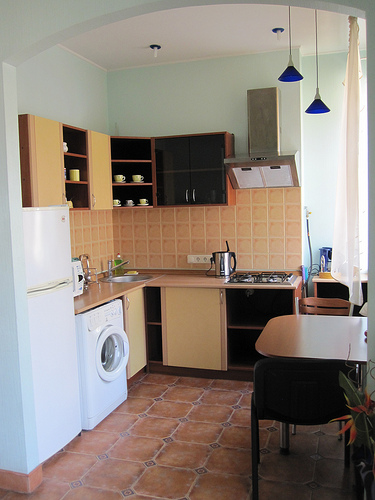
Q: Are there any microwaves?
A: Yes, there is a microwave.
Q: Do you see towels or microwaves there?
A: Yes, there is a microwave.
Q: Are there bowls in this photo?
A: No, there are no bowls.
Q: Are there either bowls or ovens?
A: No, there are no bowls or ovens.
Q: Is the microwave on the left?
A: Yes, the microwave is on the left of the image.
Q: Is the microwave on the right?
A: No, the microwave is on the left of the image.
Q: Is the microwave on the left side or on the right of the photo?
A: The microwave is on the left of the image.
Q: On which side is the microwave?
A: The microwave is on the left of the image.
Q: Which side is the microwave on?
A: The microwave is on the left of the image.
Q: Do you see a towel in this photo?
A: No, there are no towels.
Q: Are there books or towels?
A: No, there are no towels or books.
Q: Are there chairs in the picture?
A: Yes, there is a chair.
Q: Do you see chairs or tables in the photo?
A: Yes, there is a chair.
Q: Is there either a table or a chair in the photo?
A: Yes, there is a chair.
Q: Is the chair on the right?
A: Yes, the chair is on the right of the image.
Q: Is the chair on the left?
A: No, the chair is on the right of the image.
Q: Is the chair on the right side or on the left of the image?
A: The chair is on the right of the image.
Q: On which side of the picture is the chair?
A: The chair is on the right of the image.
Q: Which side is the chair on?
A: The chair is on the right of the image.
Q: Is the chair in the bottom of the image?
A: Yes, the chair is in the bottom of the image.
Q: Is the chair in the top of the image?
A: No, the chair is in the bottom of the image.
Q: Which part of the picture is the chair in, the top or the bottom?
A: The chair is in the bottom of the image.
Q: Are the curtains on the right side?
A: Yes, the curtains are on the right of the image.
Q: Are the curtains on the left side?
A: No, the curtains are on the right of the image.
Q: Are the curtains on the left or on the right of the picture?
A: The curtains are on the right of the image.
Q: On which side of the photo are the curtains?
A: The curtains are on the right of the image.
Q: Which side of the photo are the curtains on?
A: The curtains are on the right of the image.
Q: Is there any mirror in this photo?
A: No, there are no mirrors.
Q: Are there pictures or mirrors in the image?
A: No, there are no mirrors or pictures.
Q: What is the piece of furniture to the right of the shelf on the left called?
A: The piece of furniture is a cupboard.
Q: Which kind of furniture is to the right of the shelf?
A: The piece of furniture is a cupboard.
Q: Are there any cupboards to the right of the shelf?
A: Yes, there is a cupboard to the right of the shelf.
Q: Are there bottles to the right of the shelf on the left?
A: No, there is a cupboard to the right of the shelf.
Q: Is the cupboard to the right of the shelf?
A: Yes, the cupboard is to the right of the shelf.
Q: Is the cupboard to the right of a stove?
A: No, the cupboard is to the right of the shelf.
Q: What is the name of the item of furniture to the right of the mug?
A: The piece of furniture is a cupboard.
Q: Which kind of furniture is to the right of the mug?
A: The piece of furniture is a cupboard.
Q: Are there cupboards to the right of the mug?
A: Yes, there is a cupboard to the right of the mug.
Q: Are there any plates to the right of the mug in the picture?
A: No, there is a cupboard to the right of the mug.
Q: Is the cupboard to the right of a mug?
A: Yes, the cupboard is to the right of a mug.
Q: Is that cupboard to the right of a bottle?
A: No, the cupboard is to the right of a mug.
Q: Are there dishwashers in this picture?
A: Yes, there is a dishwasher.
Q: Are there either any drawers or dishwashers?
A: Yes, there is a dishwasher.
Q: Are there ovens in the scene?
A: No, there are no ovens.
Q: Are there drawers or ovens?
A: No, there are no ovens or drawers.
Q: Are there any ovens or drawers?
A: No, there are no ovens or drawers.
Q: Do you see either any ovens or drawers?
A: No, there are no ovens or drawers.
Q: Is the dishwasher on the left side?
A: Yes, the dishwasher is on the left of the image.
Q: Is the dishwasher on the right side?
A: No, the dishwasher is on the left of the image.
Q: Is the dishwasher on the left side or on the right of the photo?
A: The dishwasher is on the left of the image.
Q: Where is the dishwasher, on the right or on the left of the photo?
A: The dishwasher is on the left of the image.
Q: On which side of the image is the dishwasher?
A: The dishwasher is on the left of the image.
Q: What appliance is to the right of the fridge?
A: The appliance is a dishwasher.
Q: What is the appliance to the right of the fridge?
A: The appliance is a dishwasher.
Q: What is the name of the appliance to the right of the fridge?
A: The appliance is a dishwasher.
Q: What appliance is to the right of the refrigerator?
A: The appliance is a dishwasher.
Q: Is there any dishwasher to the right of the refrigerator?
A: Yes, there is a dishwasher to the right of the refrigerator.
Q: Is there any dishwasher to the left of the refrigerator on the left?
A: No, the dishwasher is to the right of the freezer.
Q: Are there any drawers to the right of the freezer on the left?
A: No, there is a dishwasher to the right of the freezer.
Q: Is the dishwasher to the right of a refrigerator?
A: Yes, the dishwasher is to the right of a refrigerator.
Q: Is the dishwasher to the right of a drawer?
A: No, the dishwasher is to the right of a refrigerator.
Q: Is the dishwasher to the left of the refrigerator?
A: No, the dishwasher is to the right of the refrigerator.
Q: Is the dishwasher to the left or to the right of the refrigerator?
A: The dishwasher is to the right of the refrigerator.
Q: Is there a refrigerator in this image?
A: Yes, there is a refrigerator.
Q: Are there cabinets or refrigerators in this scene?
A: Yes, there is a refrigerator.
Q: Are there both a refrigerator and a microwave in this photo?
A: Yes, there are both a refrigerator and a microwave.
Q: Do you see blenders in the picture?
A: No, there are no blenders.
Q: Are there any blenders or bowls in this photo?
A: No, there are no blenders or bowls.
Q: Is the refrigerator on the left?
A: Yes, the refrigerator is on the left of the image.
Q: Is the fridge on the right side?
A: No, the fridge is on the left of the image.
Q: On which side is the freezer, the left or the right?
A: The freezer is on the left of the image.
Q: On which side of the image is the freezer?
A: The freezer is on the left of the image.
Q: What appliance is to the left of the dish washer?
A: The appliance is a refrigerator.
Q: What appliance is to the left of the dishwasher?
A: The appliance is a refrigerator.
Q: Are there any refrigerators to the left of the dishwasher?
A: Yes, there is a refrigerator to the left of the dishwasher.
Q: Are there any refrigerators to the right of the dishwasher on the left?
A: No, the refrigerator is to the left of the dishwasher.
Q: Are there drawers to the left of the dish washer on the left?
A: No, there is a refrigerator to the left of the dishwasher.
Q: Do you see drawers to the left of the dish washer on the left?
A: No, there is a refrigerator to the left of the dishwasher.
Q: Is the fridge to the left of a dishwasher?
A: Yes, the fridge is to the left of a dishwasher.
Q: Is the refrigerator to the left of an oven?
A: No, the refrigerator is to the left of a dishwasher.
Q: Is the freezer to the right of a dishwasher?
A: No, the freezer is to the left of a dishwasher.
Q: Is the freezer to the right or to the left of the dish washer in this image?
A: The freezer is to the left of the dish washer.